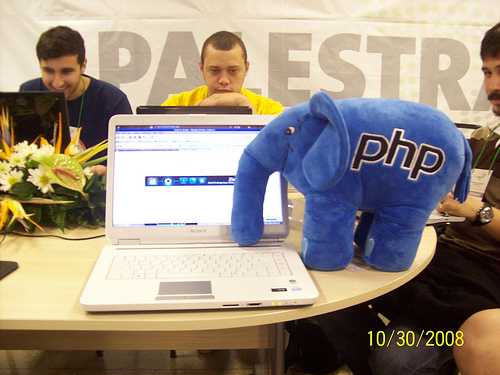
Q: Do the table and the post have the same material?
A: No, the table is made of wood and the post is made of metal.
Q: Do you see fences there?
A: No, there are no fences.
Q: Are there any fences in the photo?
A: No, there are no fences.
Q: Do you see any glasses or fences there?
A: No, there are no fences or glasses.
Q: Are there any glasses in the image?
A: No, there are no glasses.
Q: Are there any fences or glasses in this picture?
A: No, there are no glasses or fences.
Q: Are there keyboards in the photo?
A: Yes, there is a keyboard.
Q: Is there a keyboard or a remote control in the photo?
A: Yes, there is a keyboard.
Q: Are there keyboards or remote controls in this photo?
A: Yes, there is a keyboard.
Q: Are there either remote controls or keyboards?
A: Yes, there is a keyboard.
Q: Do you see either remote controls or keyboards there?
A: Yes, there is a keyboard.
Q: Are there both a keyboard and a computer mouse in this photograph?
A: No, there is a keyboard but no computer mice.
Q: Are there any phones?
A: No, there are no phones.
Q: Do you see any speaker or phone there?
A: No, there are no phones or speakers.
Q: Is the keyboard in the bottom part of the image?
A: Yes, the keyboard is in the bottom of the image.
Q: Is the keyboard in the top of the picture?
A: No, the keyboard is in the bottom of the image.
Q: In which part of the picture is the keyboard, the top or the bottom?
A: The keyboard is in the bottom of the image.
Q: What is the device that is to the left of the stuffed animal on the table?
A: The device is a keyboard.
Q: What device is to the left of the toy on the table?
A: The device is a keyboard.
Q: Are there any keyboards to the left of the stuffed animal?
A: Yes, there is a keyboard to the left of the stuffed animal.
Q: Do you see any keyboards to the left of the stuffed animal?
A: Yes, there is a keyboard to the left of the stuffed animal.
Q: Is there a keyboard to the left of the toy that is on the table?
A: Yes, there is a keyboard to the left of the stuffed animal.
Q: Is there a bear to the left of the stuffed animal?
A: No, there is a keyboard to the left of the stuffed animal.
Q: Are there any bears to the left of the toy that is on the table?
A: No, there is a keyboard to the left of the stuffed animal.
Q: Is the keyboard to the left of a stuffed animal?
A: Yes, the keyboard is to the left of a stuffed animal.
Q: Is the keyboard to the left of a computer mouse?
A: No, the keyboard is to the left of a stuffed animal.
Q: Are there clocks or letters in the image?
A: Yes, there are letters.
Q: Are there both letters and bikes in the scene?
A: No, there are letters but no bikes.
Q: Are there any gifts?
A: No, there are no gifts.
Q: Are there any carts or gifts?
A: No, there are no gifts or carts.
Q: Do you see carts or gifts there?
A: No, there are no gifts or carts.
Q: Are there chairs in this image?
A: No, there are no chairs.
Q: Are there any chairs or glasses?
A: No, there are no chairs or glasses.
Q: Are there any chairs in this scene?
A: No, there are no chairs.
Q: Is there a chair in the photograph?
A: No, there are no chairs.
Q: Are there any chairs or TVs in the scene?
A: No, there are no chairs or tvs.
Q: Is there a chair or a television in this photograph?
A: No, there are no chairs or televisions.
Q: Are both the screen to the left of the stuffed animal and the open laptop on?
A: Yes, both the screen and the laptop are on.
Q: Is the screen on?
A: Yes, the screen is on.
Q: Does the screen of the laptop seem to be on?
A: Yes, the screen is on.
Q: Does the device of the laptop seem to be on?
A: Yes, the screen is on.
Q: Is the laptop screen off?
A: No, the screen is on.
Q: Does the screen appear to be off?
A: No, the screen is on.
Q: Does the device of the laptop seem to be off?
A: No, the screen is on.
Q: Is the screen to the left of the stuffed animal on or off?
A: The screen is on.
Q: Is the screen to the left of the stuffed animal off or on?
A: The screen is on.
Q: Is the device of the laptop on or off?
A: The screen is on.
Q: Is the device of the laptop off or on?
A: The screen is on.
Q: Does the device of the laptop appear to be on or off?
A: The screen is on.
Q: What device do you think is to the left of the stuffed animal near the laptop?
A: The device is a screen.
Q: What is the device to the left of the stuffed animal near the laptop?
A: The device is a screen.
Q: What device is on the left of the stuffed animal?
A: The device is a screen.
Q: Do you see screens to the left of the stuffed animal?
A: Yes, there is a screen to the left of the stuffed animal.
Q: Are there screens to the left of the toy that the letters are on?
A: Yes, there is a screen to the left of the stuffed animal.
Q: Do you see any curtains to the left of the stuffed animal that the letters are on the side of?
A: No, there is a screen to the left of the stuffed animal.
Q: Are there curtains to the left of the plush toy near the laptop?
A: No, there is a screen to the left of the stuffed animal.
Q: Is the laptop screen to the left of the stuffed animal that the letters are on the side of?
A: Yes, the screen is to the left of the stuffed animal.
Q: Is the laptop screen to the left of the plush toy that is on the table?
A: Yes, the screen is to the left of the stuffed animal.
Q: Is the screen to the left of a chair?
A: No, the screen is to the left of the stuffed animal.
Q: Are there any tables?
A: Yes, there is a table.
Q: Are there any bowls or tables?
A: Yes, there is a table.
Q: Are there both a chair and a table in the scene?
A: No, there is a table but no chairs.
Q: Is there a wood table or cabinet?
A: Yes, there is a wood table.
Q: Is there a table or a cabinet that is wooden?
A: Yes, the table is wooden.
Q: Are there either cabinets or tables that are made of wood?
A: Yes, the table is made of wood.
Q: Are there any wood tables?
A: Yes, there is a wood table.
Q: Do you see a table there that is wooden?
A: Yes, there is a table that is wooden.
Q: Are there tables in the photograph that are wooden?
A: Yes, there is a table that is wooden.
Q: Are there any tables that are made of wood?
A: Yes, there is a table that is made of wood.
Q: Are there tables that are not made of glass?
A: Yes, there is a table that is made of wood.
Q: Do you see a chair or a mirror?
A: No, there are no chairs or mirrors.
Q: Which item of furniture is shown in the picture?
A: The piece of furniture is a table.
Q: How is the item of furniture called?
A: The piece of furniture is a table.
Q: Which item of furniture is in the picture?
A: The piece of furniture is a table.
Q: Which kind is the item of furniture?
A: The piece of furniture is a table.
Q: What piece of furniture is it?
A: The piece of furniture is a table.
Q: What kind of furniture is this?
A: This is a table.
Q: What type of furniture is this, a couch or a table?
A: This is a table.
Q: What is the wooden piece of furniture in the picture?
A: The piece of furniture is a table.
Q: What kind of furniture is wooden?
A: The furniture is a table.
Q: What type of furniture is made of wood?
A: The furniture is a table.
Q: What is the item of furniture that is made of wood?
A: The piece of furniture is a table.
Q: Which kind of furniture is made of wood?
A: The furniture is a table.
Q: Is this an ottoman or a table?
A: This is a table.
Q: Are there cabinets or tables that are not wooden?
A: No, there is a table but it is wooden.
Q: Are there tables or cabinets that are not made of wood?
A: No, there is a table but it is made of wood.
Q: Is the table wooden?
A: Yes, the table is wooden.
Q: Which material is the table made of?
A: The table is made of wood.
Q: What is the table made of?
A: The table is made of wood.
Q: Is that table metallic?
A: No, the table is wooden.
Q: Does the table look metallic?
A: No, the table is wooden.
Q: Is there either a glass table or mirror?
A: No, there is a table but it is wooden.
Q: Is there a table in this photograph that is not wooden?
A: No, there is a table but it is wooden.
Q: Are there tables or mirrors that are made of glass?
A: No, there is a table but it is made of wood.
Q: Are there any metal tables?
A: No, there is a table but it is made of wood.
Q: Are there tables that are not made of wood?
A: No, there is a table but it is made of wood.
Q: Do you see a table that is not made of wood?
A: No, there is a table but it is made of wood.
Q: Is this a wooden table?
A: Yes, this is a wooden table.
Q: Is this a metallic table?
A: No, this is a wooden table.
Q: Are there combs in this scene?
A: No, there are no combs.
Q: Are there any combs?
A: No, there are no combs.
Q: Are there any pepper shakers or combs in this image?
A: No, there are no combs or pepper shakers.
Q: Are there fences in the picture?
A: No, there are no fences.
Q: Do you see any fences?
A: No, there are no fences.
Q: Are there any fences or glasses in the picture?
A: No, there are no fences or glasses.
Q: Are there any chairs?
A: No, there are no chairs.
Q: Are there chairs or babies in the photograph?
A: No, there are no chairs or babies.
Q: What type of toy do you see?
A: The toy is a stuffed animal.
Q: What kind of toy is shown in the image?
A: The toy is a stuffed animal.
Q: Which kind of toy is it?
A: The toy is a stuffed animal.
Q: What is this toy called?
A: This is a stuffed animal.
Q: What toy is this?
A: This is a stuffed animal.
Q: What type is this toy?
A: This is a stuffed animal.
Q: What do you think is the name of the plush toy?
A: The toy is a stuffed animal.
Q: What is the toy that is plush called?
A: The toy is a stuffed animal.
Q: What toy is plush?
A: The toy is a stuffed animal.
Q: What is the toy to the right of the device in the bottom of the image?
A: The toy is a stuffed animal.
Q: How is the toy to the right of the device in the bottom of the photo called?
A: The toy is a stuffed animal.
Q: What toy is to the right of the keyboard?
A: The toy is a stuffed animal.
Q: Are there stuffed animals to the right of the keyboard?
A: Yes, there is a stuffed animal to the right of the keyboard.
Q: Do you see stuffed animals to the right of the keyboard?
A: Yes, there is a stuffed animal to the right of the keyboard.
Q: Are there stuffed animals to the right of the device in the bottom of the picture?
A: Yes, there is a stuffed animal to the right of the keyboard.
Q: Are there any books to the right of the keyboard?
A: No, there is a stuffed animal to the right of the keyboard.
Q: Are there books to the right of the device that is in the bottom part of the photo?
A: No, there is a stuffed animal to the right of the keyboard.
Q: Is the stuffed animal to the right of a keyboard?
A: Yes, the stuffed animal is to the right of a keyboard.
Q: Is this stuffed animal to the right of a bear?
A: No, the stuffed animal is to the right of a keyboard.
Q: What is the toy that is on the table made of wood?
A: The toy is a stuffed animal.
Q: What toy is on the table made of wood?
A: The toy is a stuffed animal.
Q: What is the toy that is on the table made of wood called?
A: The toy is a stuffed animal.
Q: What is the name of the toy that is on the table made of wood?
A: The toy is a stuffed animal.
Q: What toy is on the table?
A: The toy is a stuffed animal.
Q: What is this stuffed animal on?
A: The stuffed animal is on the table.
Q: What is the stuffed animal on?
A: The stuffed animal is on the table.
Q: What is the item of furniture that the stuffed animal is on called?
A: The piece of furniture is a table.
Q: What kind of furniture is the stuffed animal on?
A: The stuffed animal is on the table.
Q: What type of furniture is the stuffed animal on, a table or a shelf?
A: The stuffed animal is on a table.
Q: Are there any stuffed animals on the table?
A: Yes, there is a stuffed animal on the table.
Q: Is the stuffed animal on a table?
A: Yes, the stuffed animal is on a table.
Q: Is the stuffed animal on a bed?
A: No, the stuffed animal is on a table.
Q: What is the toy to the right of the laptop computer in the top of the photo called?
A: The toy is a stuffed animal.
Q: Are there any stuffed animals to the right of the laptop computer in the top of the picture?
A: Yes, there is a stuffed animal to the right of the laptop.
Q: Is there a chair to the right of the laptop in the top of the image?
A: No, there is a stuffed animal to the right of the laptop.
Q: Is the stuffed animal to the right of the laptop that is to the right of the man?
A: Yes, the stuffed animal is to the right of the laptop computer.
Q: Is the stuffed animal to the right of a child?
A: No, the stuffed animal is to the right of the laptop computer.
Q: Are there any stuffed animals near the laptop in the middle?
A: Yes, there is a stuffed animal near the laptop.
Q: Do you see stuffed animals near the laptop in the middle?
A: Yes, there is a stuffed animal near the laptop.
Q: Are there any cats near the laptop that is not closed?
A: No, there is a stuffed animal near the laptop computer.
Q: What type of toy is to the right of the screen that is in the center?
A: The toy is a stuffed animal.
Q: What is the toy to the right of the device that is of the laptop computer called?
A: The toy is a stuffed animal.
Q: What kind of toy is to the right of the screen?
A: The toy is a stuffed animal.